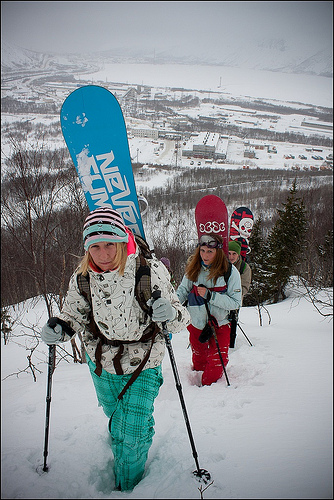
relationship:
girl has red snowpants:
[176, 233, 242, 387] [186, 326, 230, 385]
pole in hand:
[39, 340, 55, 474] [36, 312, 71, 345]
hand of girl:
[36, 312, 71, 345] [41, 205, 192, 482]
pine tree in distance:
[262, 175, 313, 282] [238, 159, 315, 313]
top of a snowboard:
[54, 62, 139, 168] [27, 54, 206, 417]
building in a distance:
[180, 129, 232, 160] [153, 120, 267, 189]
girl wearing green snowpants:
[38, 194, 190, 493] [88, 357, 175, 420]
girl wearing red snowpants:
[176, 233, 242, 387] [186, 324, 233, 385]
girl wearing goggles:
[185, 234, 242, 388] [198, 235, 219, 247]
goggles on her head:
[198, 235, 219, 247] [197, 235, 220, 266]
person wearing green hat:
[223, 238, 274, 363] [227, 240, 241, 260]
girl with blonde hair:
[65, 200, 183, 481] [78, 243, 126, 276]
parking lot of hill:
[229, 135, 332, 168] [154, 155, 327, 285]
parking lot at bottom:
[229, 135, 332, 168] [231, 125, 313, 214]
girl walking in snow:
[38, 194, 190, 493] [46, 328, 285, 496]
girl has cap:
[38, 194, 190, 493] [80, 204, 131, 254]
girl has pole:
[38, 194, 190, 493] [135, 298, 217, 467]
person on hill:
[220, 238, 251, 349] [0, 281, 334, 499]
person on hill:
[167, 231, 244, 389] [0, 281, 334, 499]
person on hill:
[37, 202, 195, 487] [0, 281, 334, 499]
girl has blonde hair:
[38, 194, 190, 493] [65, 240, 129, 278]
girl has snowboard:
[176, 233, 242, 387] [189, 186, 232, 248]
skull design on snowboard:
[232, 216, 254, 247] [229, 207, 253, 252]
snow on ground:
[93, 61, 332, 117] [6, 37, 332, 251]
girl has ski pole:
[38, 194, 190, 493] [154, 319, 215, 482]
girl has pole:
[38, 194, 190, 493] [41, 316, 56, 471]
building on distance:
[180, 132, 231, 161] [114, 78, 328, 163]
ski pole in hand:
[149, 289, 211, 494] [146, 286, 173, 328]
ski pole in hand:
[151, 285, 201, 479] [148, 296, 177, 322]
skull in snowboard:
[222, 216, 252, 237] [227, 207, 255, 263]